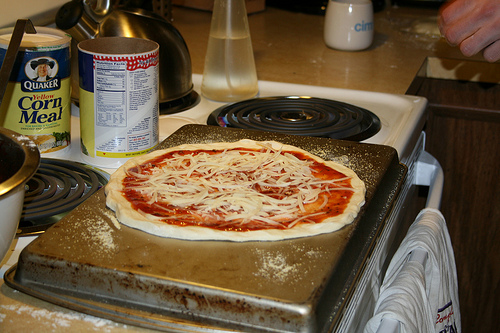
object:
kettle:
[56, 1, 201, 115]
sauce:
[331, 191, 351, 208]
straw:
[220, 1, 238, 90]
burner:
[205, 94, 383, 142]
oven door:
[312, 125, 429, 332]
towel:
[364, 206, 462, 332]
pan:
[3, 122, 409, 333]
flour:
[81, 221, 114, 250]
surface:
[28, 123, 408, 304]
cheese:
[102, 137, 367, 243]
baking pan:
[2, 122, 407, 332]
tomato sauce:
[240, 223, 256, 231]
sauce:
[141, 205, 157, 213]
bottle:
[199, 0, 260, 103]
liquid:
[200, 30, 261, 103]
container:
[0, 26, 75, 154]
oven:
[0, 71, 443, 332]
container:
[76, 35, 161, 170]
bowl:
[0, 124, 43, 262]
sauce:
[320, 166, 333, 172]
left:
[0, 0, 80, 332]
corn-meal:
[16, 93, 65, 125]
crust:
[158, 228, 207, 241]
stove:
[0, 71, 447, 332]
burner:
[16, 156, 116, 237]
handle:
[375, 144, 446, 332]